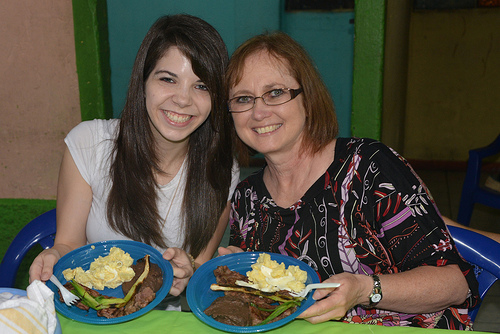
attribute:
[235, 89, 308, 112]
eyeglasses — pair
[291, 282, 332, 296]
fork — plastic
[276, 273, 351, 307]
fork — plastic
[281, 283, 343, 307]
fork — white, plastic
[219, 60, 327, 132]
woman — smiling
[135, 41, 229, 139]
woman — smiling